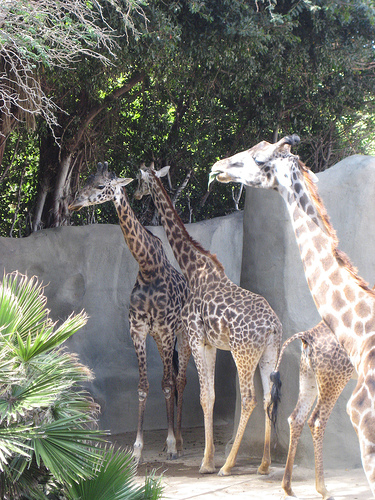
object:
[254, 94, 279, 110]
wall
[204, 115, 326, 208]
head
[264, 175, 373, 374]
neck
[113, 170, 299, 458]
animal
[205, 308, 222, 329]
spot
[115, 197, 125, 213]
fur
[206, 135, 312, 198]
head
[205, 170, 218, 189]
food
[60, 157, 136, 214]
giraffe face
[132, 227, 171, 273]
spots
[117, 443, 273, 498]
shadow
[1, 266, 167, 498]
plants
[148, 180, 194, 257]
long neck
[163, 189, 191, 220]
fur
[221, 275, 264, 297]
back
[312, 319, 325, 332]
back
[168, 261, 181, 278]
back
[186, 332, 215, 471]
leg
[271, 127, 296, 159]
horns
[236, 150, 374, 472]
wall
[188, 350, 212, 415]
giraffe leg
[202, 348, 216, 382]
giraffe leg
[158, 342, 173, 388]
giraffe leg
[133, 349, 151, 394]
giraffe leg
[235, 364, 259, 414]
giraffe leg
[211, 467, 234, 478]
hoof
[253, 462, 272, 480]
hoof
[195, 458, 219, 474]
hoof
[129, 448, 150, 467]
hoof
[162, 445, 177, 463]
hoof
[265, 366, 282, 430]
tail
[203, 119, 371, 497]
giraffe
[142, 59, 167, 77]
wall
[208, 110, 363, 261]
giraffe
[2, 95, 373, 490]
giraffes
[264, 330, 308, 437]
tail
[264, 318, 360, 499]
giraffe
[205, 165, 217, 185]
leaf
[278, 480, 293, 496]
hoof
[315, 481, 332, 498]
hoof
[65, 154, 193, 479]
giraffe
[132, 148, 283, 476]
giraffe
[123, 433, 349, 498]
ground